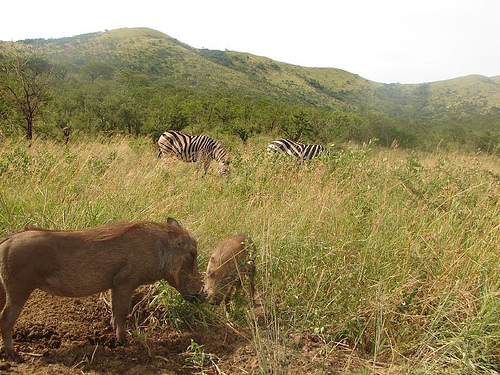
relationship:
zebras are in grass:
[154, 129, 231, 176] [3, 133, 497, 374]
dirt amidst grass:
[0, 288, 363, 374] [3, 133, 497, 374]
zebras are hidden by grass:
[154, 129, 231, 176] [3, 133, 497, 374]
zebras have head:
[154, 129, 231, 176] [217, 146, 233, 176]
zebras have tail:
[154, 129, 231, 176] [154, 132, 163, 156]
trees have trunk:
[1, 47, 55, 139] [25, 108, 34, 144]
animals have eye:
[1, 216, 205, 359] [189, 248, 196, 260]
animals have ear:
[1, 216, 205, 359] [165, 215, 185, 245]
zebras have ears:
[154, 129, 231, 176] [226, 145, 233, 154]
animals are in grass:
[1, 216, 205, 359] [3, 133, 497, 374]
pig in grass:
[201, 235, 259, 301] [3, 133, 497, 374]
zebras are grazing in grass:
[154, 129, 231, 176] [3, 133, 497, 374]